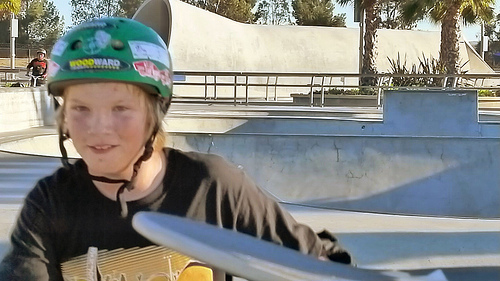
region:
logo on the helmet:
[65, 58, 129, 75]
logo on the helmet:
[130, 42, 170, 67]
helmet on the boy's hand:
[43, 17, 177, 94]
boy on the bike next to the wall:
[27, 49, 48, 86]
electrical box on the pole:
[8, 12, 17, 43]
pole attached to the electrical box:
[12, 35, 15, 82]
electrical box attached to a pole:
[483, 34, 488, 53]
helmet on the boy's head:
[37, 48, 46, 54]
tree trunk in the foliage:
[441, 12, 461, 85]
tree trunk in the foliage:
[360, 4, 377, 94]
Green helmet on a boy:
[44, 16, 174, 111]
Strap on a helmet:
[52, 98, 180, 185]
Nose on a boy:
[86, 99, 112, 139]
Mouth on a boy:
[79, 135, 119, 161]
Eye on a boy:
[101, 99, 141, 120]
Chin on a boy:
[72, 135, 153, 174]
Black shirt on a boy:
[3, 149, 315, 279]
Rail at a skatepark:
[198, 59, 398, 112]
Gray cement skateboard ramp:
[229, 122, 421, 228]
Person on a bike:
[29, 44, 50, 91]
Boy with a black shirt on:
[0, 11, 360, 279]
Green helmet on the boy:
[38, 14, 183, 106]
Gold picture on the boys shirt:
[52, 236, 229, 279]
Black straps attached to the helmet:
[47, 89, 165, 219]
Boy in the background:
[20, 45, 53, 87]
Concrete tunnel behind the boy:
[128, 0, 498, 102]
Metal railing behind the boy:
[1, 61, 498, 121]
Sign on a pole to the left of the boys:
[3, 5, 21, 84]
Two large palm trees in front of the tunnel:
[349, 0, 498, 102]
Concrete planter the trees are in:
[287, 86, 499, 113]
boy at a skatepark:
[17, 0, 414, 277]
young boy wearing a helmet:
[30, 17, 190, 194]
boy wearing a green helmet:
[32, 7, 180, 186]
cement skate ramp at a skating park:
[271, 115, 453, 232]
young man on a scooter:
[21, 50, 48, 89]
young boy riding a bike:
[22, 48, 45, 89]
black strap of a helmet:
[112, 174, 132, 218]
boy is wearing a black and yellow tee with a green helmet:
[17, 14, 232, 277]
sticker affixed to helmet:
[65, 55, 122, 77]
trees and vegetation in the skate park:
[348, 4, 492, 101]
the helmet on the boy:
[44, 17, 171, 217]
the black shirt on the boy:
[0, 145, 322, 278]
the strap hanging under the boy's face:
[50, 95, 160, 219]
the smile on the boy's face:
[85, 140, 120, 152]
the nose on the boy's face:
[87, 108, 111, 137]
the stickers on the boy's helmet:
[46, 17, 171, 96]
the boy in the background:
[25, 47, 48, 84]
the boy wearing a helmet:
[3, 17, 320, 279]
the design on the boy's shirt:
[61, 239, 213, 279]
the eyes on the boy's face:
[70, 102, 130, 114]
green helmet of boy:
[42, 21, 181, 107]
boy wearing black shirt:
[10, 20, 355, 275]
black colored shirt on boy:
[15, 150, 345, 275]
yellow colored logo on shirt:
[40, 235, 200, 275]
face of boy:
[55, 80, 160, 170]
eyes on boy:
[50, 95, 130, 115]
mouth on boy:
[70, 135, 125, 155]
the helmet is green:
[45, 16, 172, 103]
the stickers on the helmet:
[45, 16, 172, 102]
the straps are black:
[52, 88, 158, 218]